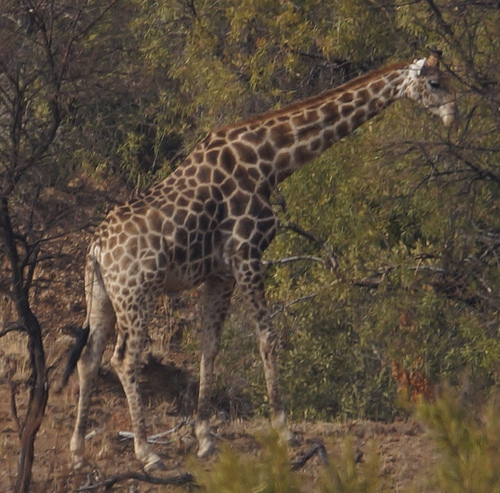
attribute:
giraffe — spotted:
[54, 47, 470, 382]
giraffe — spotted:
[43, 40, 493, 364]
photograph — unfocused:
[6, 0, 486, 481]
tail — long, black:
[2, 281, 110, 391]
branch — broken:
[103, 400, 284, 487]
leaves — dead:
[369, 324, 444, 418]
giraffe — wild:
[51, 25, 489, 419]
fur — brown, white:
[85, 93, 357, 364]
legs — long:
[188, 256, 308, 460]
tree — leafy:
[65, 50, 480, 330]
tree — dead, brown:
[1, 24, 121, 446]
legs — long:
[197, 272, 306, 461]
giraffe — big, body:
[68, 49, 458, 468]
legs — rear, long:
[68, 258, 161, 467]